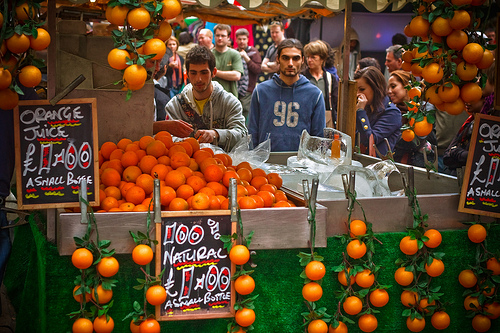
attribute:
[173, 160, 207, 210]
orange orange — round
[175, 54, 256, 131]
man — giving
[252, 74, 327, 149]
shirt — blue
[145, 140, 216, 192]
oranges — multiple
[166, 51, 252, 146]
person — bunched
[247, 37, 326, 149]
person — short haired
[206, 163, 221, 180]
orange — round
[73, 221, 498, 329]
oranges — hanging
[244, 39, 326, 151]
shirt — blue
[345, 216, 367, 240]
orange — round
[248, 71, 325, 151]
sweatshirt — blue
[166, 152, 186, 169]
orange — round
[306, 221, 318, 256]
vine — orange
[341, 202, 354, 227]
vine — orange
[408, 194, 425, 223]
vine — orange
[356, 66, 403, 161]
people — crowd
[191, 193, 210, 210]
oranges — several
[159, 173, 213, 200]
orange — round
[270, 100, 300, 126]
number — 96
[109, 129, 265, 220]
oranges — piled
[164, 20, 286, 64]
patrons — watching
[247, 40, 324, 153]
man — wearing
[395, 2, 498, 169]
oranges — hanging, above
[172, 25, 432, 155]
people — grouped, shopping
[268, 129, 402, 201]
equipment — squeezing